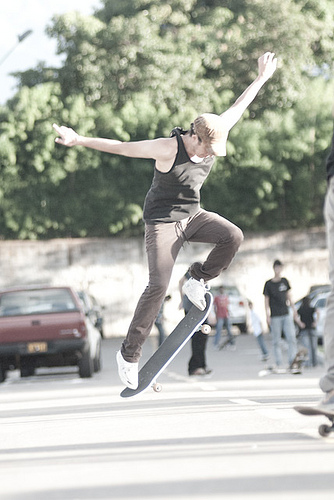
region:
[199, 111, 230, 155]
A brown cap in the photo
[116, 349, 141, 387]
White shoes on the skate board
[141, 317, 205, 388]
A skate board in the air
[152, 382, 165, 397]
A wheel of a skate board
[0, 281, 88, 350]
A red car in the background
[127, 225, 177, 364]
brown pants in the photo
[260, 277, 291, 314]
Black shirts in the photo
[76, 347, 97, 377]
Car wheel in the background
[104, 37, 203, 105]
Trees in the photo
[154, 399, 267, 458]
A road with tarmac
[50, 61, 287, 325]
this is a boy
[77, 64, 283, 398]
the boy is skating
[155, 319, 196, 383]
this is a skate board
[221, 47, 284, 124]
the hand is raised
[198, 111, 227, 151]
he is wearing a cap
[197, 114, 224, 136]
the cap is brown in color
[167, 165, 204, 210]
he is wearing a avest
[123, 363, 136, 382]
the shoe is white in color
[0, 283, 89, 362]
the car is parked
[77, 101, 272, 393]
the boy is on air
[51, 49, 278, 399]
a skateboarder performing trick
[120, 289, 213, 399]
a black and white skateboard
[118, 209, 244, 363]
a brown pair of jeans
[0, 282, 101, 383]
a parked red car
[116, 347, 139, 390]
a white athletic shoe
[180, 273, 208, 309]
a white athletic shoe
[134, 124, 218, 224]
a black tank top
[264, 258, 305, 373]
a skateboarder in distance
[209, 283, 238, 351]
a skateboarder in distance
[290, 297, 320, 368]
a woman standing in distance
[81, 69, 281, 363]
this is a man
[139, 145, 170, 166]
the man is light skinned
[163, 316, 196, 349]
this is a skate board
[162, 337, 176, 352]
the board is black in color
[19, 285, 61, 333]
this is a car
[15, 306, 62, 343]
the car is red in color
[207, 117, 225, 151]
this is a cap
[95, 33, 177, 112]
this is a tree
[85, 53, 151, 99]
thew leaves are green in color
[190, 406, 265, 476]
this is the road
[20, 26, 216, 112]
The background is blurry.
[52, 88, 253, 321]
The man is in focus.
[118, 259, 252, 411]
The man is skateboarding.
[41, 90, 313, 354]
The man is in motion.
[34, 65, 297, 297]
The man is in the air.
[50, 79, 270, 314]
The man is doing a trick.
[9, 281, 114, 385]
This is a vehicle.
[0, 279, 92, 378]
The car is red.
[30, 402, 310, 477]
The ground here is concrete.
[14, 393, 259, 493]
The concrete is gray and white.